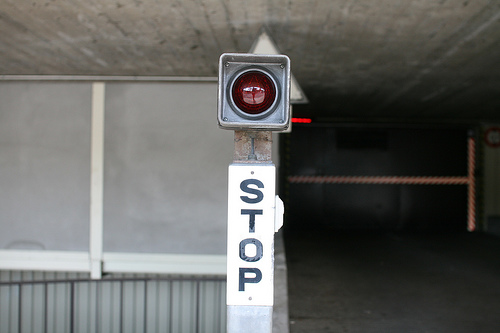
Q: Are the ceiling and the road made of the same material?
A: Yes, both the ceiling and the road are made of concrete.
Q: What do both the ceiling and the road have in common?
A: The material, both the ceiling and the road are concrete.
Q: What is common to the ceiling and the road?
A: The material, both the ceiling and the road are concrete.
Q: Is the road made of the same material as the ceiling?
A: Yes, both the road and the ceiling are made of concrete.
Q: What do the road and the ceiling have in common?
A: The material, both the road and the ceiling are concrete.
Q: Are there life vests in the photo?
A: No, there are no life vests.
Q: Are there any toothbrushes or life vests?
A: No, there are no life vests or toothbrushes.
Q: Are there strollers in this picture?
A: No, there are no strollers.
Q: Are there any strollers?
A: No, there are no strollers.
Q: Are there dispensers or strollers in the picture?
A: No, there are no strollers or dispensers.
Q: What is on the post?
A: The letter is on the post.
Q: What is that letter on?
A: The letter is on the post.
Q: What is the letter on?
A: The letter is on the post.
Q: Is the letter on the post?
A: Yes, the letter is on the post.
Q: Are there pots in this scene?
A: No, there are no pots.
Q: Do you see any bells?
A: No, there are no bells.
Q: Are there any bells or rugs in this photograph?
A: No, there are no bells or rugs.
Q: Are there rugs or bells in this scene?
A: No, there are no bells or rugs.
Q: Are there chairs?
A: No, there are no chairs.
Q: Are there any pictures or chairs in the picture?
A: No, there are no chairs or pictures.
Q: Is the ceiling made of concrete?
A: Yes, the ceiling is made of concrete.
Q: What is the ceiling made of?
A: The ceiling is made of concrete.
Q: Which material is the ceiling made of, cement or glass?
A: The ceiling is made of cement.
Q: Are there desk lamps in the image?
A: No, there are no desk lamps.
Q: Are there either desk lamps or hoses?
A: No, there are no desk lamps or hoses.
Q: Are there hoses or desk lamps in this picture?
A: No, there are no desk lamps or hoses.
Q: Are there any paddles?
A: No, there are no paddles.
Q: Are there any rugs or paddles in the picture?
A: No, there are no paddles or rugs.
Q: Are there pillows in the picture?
A: No, there are no pillows.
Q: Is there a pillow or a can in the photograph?
A: No, there are no pillows or cans.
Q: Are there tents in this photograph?
A: No, there are no tents.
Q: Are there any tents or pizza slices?
A: No, there are no tents or pizza slices.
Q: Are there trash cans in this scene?
A: No, there are no trash cans.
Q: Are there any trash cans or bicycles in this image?
A: No, there are no trash cans or bicycles.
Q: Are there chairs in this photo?
A: No, there are no chairs.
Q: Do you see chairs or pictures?
A: No, there are no chairs or pictures.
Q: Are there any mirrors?
A: No, there are no mirrors.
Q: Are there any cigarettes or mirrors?
A: No, there are no mirrors or cigarettes.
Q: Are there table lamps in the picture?
A: No, there are no table lamps.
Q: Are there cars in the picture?
A: No, there are no cars.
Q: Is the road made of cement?
A: Yes, the road is made of cement.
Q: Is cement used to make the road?
A: Yes, the road is made of cement.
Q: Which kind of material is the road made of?
A: The road is made of cement.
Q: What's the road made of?
A: The road is made of concrete.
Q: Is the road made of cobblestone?
A: No, the road is made of cement.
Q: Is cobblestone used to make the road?
A: No, the road is made of cement.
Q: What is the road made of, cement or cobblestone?
A: The road is made of cement.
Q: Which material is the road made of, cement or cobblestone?
A: The road is made of cement.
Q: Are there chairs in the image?
A: No, there are no chairs.